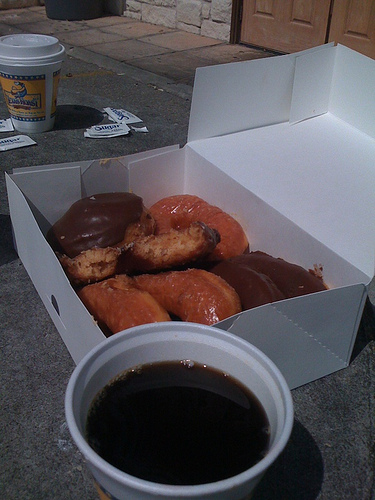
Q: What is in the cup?
A: Drink.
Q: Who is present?
A: Nobody.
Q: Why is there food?
A: For eating.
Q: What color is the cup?
A: White.